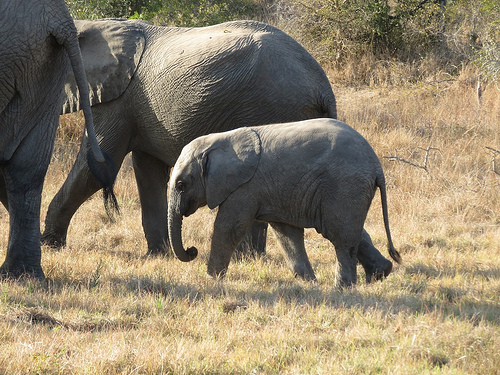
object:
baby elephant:
[166, 117, 403, 291]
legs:
[327, 210, 387, 270]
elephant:
[164, 115, 405, 290]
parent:
[0, 0, 122, 284]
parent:
[41, 16, 334, 259]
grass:
[0, 0, 498, 374]